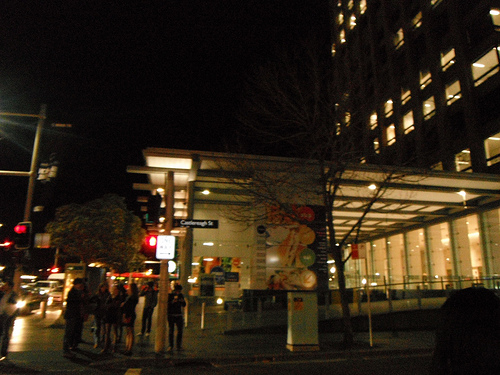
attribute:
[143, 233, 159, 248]
stop light — red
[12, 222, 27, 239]
stop light — red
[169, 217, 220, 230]
street sign — black, white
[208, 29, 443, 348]
tree — bare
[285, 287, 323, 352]
electrical box — square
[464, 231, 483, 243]
light — on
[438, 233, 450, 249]
light — on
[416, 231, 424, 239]
light — on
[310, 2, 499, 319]
building — white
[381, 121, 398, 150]
window — lit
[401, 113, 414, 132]
window — lit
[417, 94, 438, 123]
window — lit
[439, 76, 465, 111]
window — lit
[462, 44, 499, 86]
window — lit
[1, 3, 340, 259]
sky — dark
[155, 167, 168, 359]
post — tall